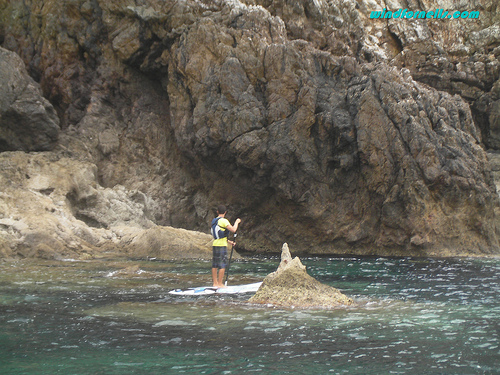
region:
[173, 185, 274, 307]
the man is paddling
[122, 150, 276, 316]
the man is paddling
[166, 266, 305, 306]
the surfboard is white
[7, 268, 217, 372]
Dark blue river running along side rocks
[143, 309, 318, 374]
Waves on the river's surface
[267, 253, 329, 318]
Brown rock jutting out of the river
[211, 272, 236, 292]
Man's legs on white surf board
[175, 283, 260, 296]
White and blue surf board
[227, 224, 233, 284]
Long black paddle in man's hands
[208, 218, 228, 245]
Blue and white life vest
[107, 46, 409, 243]
Large rock mountain formation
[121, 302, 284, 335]
Brown sand bar in river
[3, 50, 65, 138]
Small cliff on rock mountain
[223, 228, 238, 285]
a black oar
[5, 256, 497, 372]
greenish gray water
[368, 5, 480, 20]
green word show a web address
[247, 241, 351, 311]
rock protruding from the water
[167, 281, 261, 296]
a white and blue surfboard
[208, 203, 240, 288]
a male with short dark hair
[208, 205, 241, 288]
a male in a yellow shirt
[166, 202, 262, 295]
male standing on a surfboard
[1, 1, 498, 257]
a bare hill of rock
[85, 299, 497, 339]
sunshine shining on the water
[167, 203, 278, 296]
Man wearing a life vest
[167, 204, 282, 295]
Man is paddle boarding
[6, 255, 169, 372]
The water is choppy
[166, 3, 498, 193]
Rocky landscape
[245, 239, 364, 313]
rocky obstacle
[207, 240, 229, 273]
man is wearing swim trunks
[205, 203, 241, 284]
man holding paddle in the water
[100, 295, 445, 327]
small sand bar near man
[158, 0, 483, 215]
large rocky cliff in background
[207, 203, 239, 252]
Man wearing yellow shirt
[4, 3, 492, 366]
a boy is paddle boarding through a gorge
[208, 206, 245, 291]
the boy is holding a paddle with both hands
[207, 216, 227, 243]
a life vest is on the person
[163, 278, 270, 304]
the paddle board is white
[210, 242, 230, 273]
the boy has dark shorts on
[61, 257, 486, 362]
the water is clear with ripples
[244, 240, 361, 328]
a rock outcropping is in the middle of the river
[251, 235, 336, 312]
the rock has pointed outcroppings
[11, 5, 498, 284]
the rocks have dark indentations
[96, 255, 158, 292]
a rock is protruding out of the water